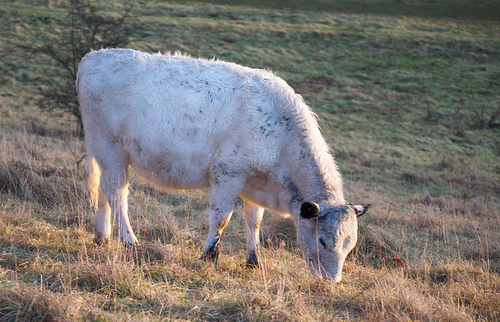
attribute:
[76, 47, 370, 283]
cow — white, eating, watching, young, standing, enjoying, relaxed, solitary, furry, grazing, dirty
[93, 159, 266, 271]
legs — short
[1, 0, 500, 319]
grass — brown, yellow, here, green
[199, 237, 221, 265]
marking — black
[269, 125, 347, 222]
neck — down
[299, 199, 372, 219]
ears — black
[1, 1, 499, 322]
picture — outdoors